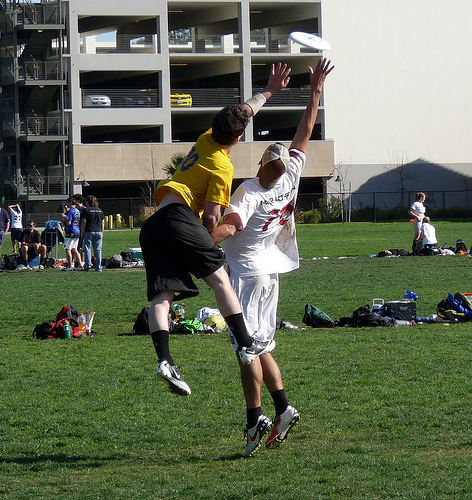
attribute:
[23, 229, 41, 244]
shirt — black 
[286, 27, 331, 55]
frisbee — white , round 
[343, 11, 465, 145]
sky — grey , cloudy 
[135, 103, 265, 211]
tshirt — yellow 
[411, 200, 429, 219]
shirt — white 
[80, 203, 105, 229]
shirt — black 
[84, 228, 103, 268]
jeans — black 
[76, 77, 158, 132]
car — white 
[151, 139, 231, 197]
shirt — black 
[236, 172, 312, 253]
shirt — blue 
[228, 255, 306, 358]
shorts — white 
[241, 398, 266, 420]
socks — black